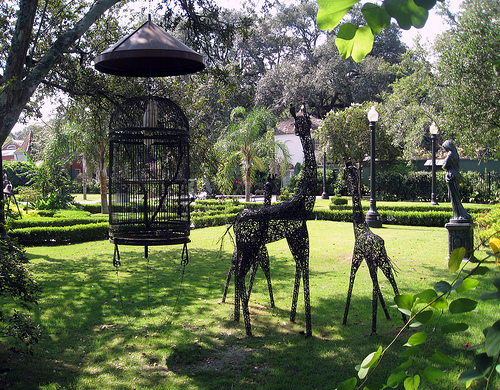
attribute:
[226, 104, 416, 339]
giraffes — statues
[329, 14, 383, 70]
leaf — green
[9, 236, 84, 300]
shrubbery — low, green, garden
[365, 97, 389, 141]
lamp — white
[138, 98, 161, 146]
bird — white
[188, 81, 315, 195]
tree — medium-size, tropical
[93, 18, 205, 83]
guard — squirrel prevention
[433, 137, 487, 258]
statue — gray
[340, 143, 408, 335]
wire giraffe — black, metal wire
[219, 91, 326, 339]
wire giraffe — black, metal wire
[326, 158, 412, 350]
giraffe — small, statue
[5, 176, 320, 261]
hedge — low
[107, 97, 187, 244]
birdcage — metal, hanging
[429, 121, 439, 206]
street lights — glass globe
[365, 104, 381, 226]
street lights — glass globe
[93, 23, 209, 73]
hood — black, metal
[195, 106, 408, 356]
statues — giraffes, black, metal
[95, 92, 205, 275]
cage — metal, bird, hanging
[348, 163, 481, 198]
hedge — green